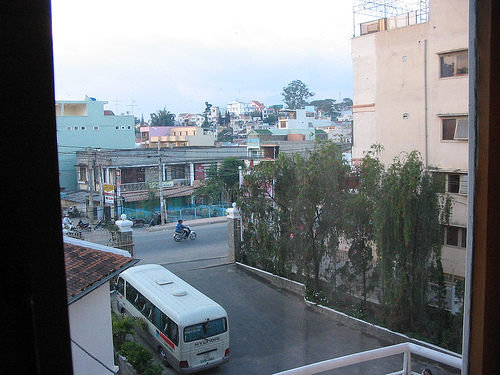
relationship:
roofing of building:
[64, 239, 132, 305] [62, 236, 139, 370]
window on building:
[439, 53, 454, 76] [342, 29, 481, 287]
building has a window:
[359, 19, 493, 330] [434, 175, 476, 211]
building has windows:
[359, 19, 493, 330] [106, 271, 229, 340]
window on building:
[278, 122, 287, 130] [271, 107, 310, 136]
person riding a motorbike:
[175, 215, 193, 232] [173, 229, 201, 249]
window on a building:
[455, 48, 470, 76] [353, 0, 470, 321]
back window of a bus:
[182, 317, 227, 344] [98, 244, 235, 368]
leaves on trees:
[403, 207, 415, 230] [373, 155, 450, 335]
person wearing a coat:
[175, 219, 191, 240] [161, 226, 200, 242]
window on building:
[72, 160, 91, 185] [68, 140, 255, 228]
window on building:
[427, 45, 473, 82] [54, 90, 145, 205]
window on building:
[308, 123, 315, 131] [53, 93, 245, 227]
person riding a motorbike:
[175, 219, 191, 240] [173, 226, 198, 243]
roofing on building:
[65, 238, 132, 310] [55, 228, 142, 373]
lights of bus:
[161, 356, 268, 373] [110, 261, 230, 370]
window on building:
[437, 108, 477, 148] [326, 8, 470, 331]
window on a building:
[453, 120, 470, 138] [351, 8, 477, 358]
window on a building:
[453, 120, 470, 138] [349, 21, 471, 309]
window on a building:
[439, 49, 464, 76] [349, 21, 471, 309]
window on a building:
[453, 120, 470, 138] [348, 0, 484, 306]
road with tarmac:
[118, 221, 418, 362] [258, 295, 296, 350]